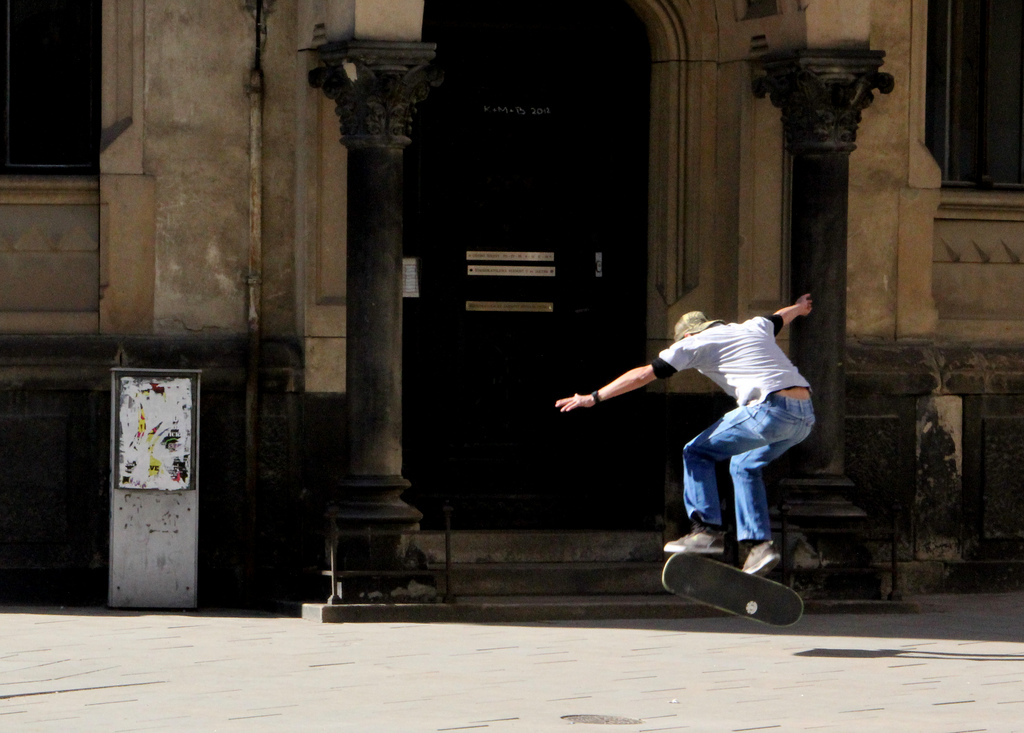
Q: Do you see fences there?
A: No, there are no fences.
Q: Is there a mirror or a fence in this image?
A: No, there are no fences or mirrors.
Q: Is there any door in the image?
A: Yes, there is a door.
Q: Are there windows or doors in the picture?
A: Yes, there is a door.